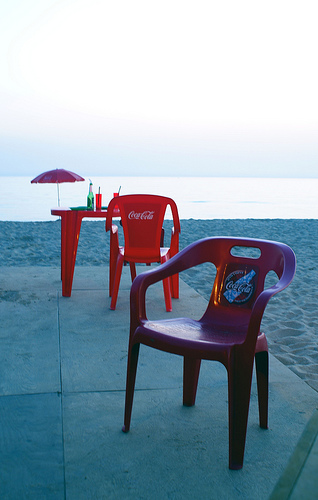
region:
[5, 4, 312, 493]
plastic chairs at the beach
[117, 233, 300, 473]
maroon chair at the beach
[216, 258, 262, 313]
Coca Cola logo on front of chair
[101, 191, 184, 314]
red chair on beach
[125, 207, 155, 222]
Coca Cola logo on back of chair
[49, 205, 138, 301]
red table on beach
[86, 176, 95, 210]
green bottle with straw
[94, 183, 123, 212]
red tumblers with straws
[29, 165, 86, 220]
red umbrella on beach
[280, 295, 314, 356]
patch of sand on beach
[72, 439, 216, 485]
A blue clean surface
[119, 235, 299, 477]
A red plastic chair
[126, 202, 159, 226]
A Cocacola sponsored chair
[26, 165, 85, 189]
A red wide umbrella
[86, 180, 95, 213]
A green glass bottle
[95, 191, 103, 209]
A red drinking glass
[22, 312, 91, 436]
A checked floor surface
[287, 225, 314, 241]
A wavy water surface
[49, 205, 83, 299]
A red plastic chair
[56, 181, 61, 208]
A long metal rod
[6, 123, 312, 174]
pale blue daytime sky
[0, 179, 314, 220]
surface of calm water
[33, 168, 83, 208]
red umbrella on pole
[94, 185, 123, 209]
two red cups with straws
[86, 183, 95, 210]
green bottle with labels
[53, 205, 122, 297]
red table with legs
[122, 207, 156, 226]
white logo on red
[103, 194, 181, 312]
back of plastic chair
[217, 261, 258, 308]
emblem on plastic surface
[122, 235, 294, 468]
red plastic chair on four legs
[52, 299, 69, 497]
Cracks on gray sidewalk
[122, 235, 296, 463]
Purple plastic chair on sidewalk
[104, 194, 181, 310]
Red plastic chair on sidewalk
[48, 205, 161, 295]
Red plastic table on sidewalk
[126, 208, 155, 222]
White letters on red chair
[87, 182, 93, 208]
Green bottle on red table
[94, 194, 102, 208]
Red cup on red plastic table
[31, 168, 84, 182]
Red umbrella on beach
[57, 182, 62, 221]
Umbrella pole on beach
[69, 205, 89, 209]
Green plate on red table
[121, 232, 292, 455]
red chair in foreground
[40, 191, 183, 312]
red chair and red table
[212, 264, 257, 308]
logo on back of chair in foreground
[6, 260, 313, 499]
cement pad chairs and table are on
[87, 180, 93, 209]
green drink bottle on red table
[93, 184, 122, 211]
two red cups on table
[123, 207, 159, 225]
white lettering on red chair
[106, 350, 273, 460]
legs of foreground chair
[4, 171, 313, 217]
ocean on the horizon